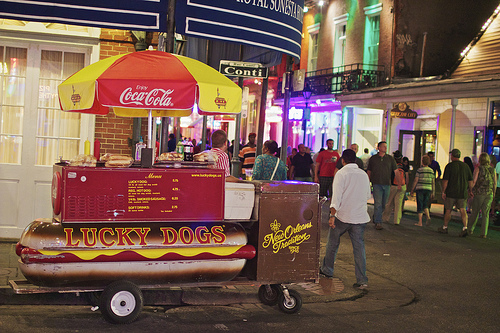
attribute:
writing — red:
[57, 223, 233, 249]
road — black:
[413, 267, 449, 311]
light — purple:
[272, 77, 390, 177]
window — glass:
[2, 44, 25, 162]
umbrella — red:
[69, 49, 324, 136]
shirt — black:
[411, 151, 492, 193]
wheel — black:
[103, 279, 145, 321]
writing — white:
[119, 84, 175, 109]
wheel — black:
[95, 281, 152, 328]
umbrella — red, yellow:
[45, 42, 259, 122]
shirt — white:
[328, 161, 381, 231]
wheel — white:
[104, 285, 163, 332]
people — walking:
[466, 150, 496, 239]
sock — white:
[461, 225, 467, 230]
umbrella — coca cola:
[39, 43, 263, 128]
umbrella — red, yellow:
[58, 49, 245, 119]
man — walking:
[364, 132, 402, 234]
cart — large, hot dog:
[0, 163, 320, 321]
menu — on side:
[64, 163, 209, 238]